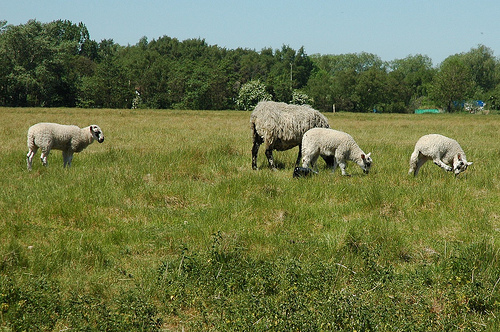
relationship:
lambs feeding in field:
[19, 91, 477, 199] [0, 173, 464, 329]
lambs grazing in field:
[19, 91, 477, 199] [0, 173, 464, 329]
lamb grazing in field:
[408, 133, 474, 177] [0, 173, 464, 329]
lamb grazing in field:
[388, 112, 496, 201] [0, 173, 464, 329]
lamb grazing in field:
[301, 127, 373, 176] [0, 173, 464, 329]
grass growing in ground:
[0, 105, 499, 332] [176, 105, 220, 189]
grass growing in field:
[0, 105, 499, 332] [0, 173, 464, 329]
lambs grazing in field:
[247, 101, 331, 172] [0, 173, 464, 329]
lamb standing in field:
[408, 133, 474, 177] [0, 173, 464, 329]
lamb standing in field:
[25, 123, 105, 173] [0, 173, 464, 329]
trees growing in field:
[0, 17, 499, 116] [0, 173, 464, 329]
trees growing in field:
[318, 53, 356, 110] [0, 173, 464, 329]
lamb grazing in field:
[25, 123, 105, 173] [0, 173, 464, 329]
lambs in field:
[247, 101, 331, 172] [1, 109, 496, 329]